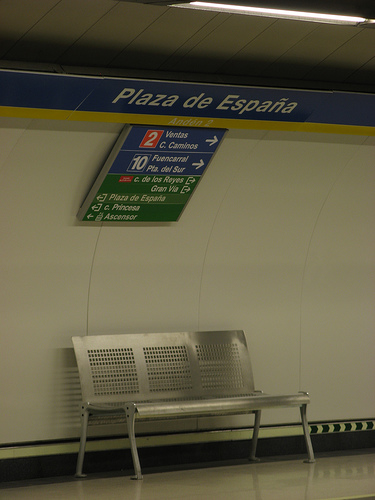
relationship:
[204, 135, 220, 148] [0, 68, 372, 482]
arrow on wall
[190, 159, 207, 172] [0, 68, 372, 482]
arrow on wall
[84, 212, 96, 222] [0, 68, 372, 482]
arrow on wall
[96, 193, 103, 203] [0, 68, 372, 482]
arrow on wall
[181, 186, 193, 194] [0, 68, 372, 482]
arrow on wall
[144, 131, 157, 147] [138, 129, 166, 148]
two on square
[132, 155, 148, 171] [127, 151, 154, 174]
ten on square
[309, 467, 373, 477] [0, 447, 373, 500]
reflection on floor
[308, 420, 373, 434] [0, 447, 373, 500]
arrows reflected on floor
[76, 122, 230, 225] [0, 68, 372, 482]
sign on wall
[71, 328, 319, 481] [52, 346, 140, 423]
bench makes shadow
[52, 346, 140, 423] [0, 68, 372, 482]
shadow on wall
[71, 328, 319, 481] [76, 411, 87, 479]
bench has leg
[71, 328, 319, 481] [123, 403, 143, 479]
bench has leg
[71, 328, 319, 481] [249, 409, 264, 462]
bench has leg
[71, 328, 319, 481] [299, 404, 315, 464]
bench has leg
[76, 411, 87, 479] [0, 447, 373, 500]
leg bolted to floor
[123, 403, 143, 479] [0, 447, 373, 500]
leg bolted to floor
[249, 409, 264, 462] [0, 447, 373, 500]
leg bolted to floor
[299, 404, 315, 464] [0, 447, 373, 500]
leg bolted to floor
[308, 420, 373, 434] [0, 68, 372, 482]
arrows on wall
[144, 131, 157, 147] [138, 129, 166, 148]
two in square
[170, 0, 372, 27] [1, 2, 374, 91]
light fixture on ceiling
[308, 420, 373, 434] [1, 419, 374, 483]
arrows on molding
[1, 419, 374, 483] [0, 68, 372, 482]
molding on wall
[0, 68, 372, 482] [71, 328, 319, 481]
wall beside bench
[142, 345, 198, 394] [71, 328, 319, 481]
section of bench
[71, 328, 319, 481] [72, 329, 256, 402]
bench has back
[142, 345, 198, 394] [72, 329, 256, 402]
section on back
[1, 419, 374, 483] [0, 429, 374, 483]
molding has stripe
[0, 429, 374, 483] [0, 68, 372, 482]
stripe on wall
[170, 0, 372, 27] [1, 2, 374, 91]
light fixture in ceiling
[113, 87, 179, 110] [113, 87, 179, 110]
plaza on plaza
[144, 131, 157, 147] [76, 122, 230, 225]
two on sign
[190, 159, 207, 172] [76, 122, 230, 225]
arrow on sign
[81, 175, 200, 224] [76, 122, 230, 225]
portion of sign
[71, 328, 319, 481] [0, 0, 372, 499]
bench in station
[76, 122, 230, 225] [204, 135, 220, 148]
sign has arrow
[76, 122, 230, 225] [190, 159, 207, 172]
sign has arrow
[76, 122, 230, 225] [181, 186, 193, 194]
sign has arrow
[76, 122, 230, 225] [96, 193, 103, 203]
sign has arrow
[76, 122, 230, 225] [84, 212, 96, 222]
sign has arrow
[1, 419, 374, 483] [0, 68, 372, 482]
molding on bottom of wall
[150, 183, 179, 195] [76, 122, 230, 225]
gran via on sign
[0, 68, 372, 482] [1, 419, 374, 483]
wall has molding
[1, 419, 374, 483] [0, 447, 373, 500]
molding next to floor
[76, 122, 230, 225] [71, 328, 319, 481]
sign above bench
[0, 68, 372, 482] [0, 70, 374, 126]
wall has stripe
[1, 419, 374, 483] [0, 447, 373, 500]
molding reflects on floor